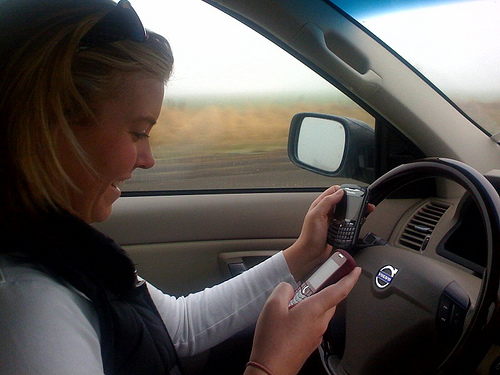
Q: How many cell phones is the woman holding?
A: Two.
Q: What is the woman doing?
A: Texting and driving.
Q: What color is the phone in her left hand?
A: Black.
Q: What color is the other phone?
A: Red.